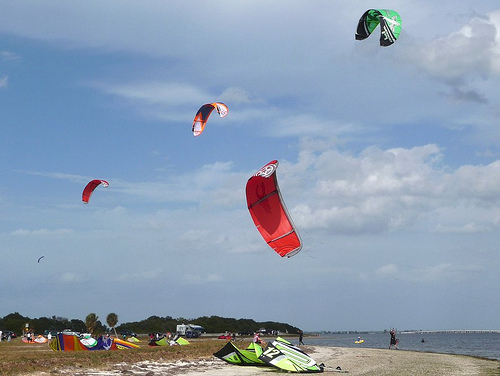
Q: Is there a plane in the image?
A: No, there are no airplanes.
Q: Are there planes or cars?
A: No, there are no planes or cars.